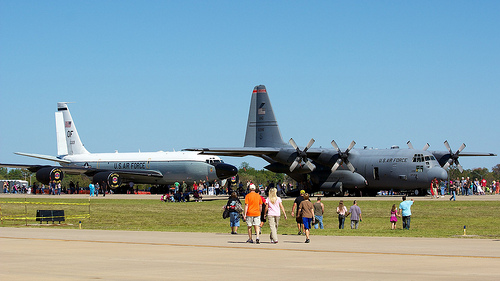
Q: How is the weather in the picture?
A: It is clear.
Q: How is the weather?
A: It is clear.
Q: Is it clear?
A: Yes, it is clear.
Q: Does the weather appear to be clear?
A: Yes, it is clear.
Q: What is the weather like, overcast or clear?
A: It is clear.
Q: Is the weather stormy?
A: No, it is clear.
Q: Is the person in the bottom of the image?
A: Yes, the person is in the bottom of the image.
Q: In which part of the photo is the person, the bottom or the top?
A: The person is in the bottom of the image.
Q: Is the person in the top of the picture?
A: No, the person is in the bottom of the image.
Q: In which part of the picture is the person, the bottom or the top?
A: The person is in the bottom of the image.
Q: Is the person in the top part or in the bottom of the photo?
A: The person is in the bottom of the image.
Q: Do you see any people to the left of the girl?
A: Yes, there is a person to the left of the girl.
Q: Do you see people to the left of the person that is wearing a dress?
A: Yes, there is a person to the left of the girl.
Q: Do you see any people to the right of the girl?
A: No, the person is to the left of the girl.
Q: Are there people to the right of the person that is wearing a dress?
A: No, the person is to the left of the girl.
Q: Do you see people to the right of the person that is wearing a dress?
A: No, the person is to the left of the girl.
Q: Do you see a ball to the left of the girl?
A: No, there is a person to the left of the girl.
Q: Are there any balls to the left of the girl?
A: No, there is a person to the left of the girl.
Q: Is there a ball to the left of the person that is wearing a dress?
A: No, there is a person to the left of the girl.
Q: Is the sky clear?
A: Yes, the sky is clear.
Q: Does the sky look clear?
A: Yes, the sky is clear.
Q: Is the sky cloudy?
A: No, the sky is clear.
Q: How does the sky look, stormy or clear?
A: The sky is clear.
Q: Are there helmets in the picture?
A: No, there are no helmets.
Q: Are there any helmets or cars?
A: No, there are no helmets or cars.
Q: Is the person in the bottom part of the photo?
A: Yes, the person is in the bottom of the image.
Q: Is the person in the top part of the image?
A: No, the person is in the bottom of the image.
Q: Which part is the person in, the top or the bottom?
A: The person is in the bottom of the image.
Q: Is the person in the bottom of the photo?
A: Yes, the person is in the bottom of the image.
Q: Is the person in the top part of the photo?
A: No, the person is in the bottom of the image.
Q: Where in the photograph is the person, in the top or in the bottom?
A: The person is in the bottom of the image.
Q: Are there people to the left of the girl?
A: Yes, there is a person to the left of the girl.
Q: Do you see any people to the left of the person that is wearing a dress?
A: Yes, there is a person to the left of the girl.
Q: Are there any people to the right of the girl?
A: No, the person is to the left of the girl.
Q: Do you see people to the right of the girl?
A: No, the person is to the left of the girl.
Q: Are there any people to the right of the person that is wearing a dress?
A: No, the person is to the left of the girl.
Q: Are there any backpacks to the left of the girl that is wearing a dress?
A: No, there is a person to the left of the girl.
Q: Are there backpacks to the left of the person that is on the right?
A: No, there is a person to the left of the girl.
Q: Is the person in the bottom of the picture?
A: Yes, the person is in the bottom of the image.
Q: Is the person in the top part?
A: No, the person is in the bottom of the image.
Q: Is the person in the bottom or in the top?
A: The person is in the bottom of the image.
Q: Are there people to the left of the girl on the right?
A: Yes, there is a person to the left of the girl.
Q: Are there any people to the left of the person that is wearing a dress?
A: Yes, there is a person to the left of the girl.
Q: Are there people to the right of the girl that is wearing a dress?
A: No, the person is to the left of the girl.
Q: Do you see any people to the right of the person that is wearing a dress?
A: No, the person is to the left of the girl.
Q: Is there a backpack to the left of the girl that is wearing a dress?
A: No, there is a person to the left of the girl.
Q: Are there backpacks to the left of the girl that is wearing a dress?
A: No, there is a person to the left of the girl.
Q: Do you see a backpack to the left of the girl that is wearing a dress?
A: No, there is a person to the left of the girl.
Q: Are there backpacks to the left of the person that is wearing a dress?
A: No, there is a person to the left of the girl.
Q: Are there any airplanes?
A: Yes, there is an airplane.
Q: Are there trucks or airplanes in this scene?
A: Yes, there is an airplane.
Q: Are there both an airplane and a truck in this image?
A: No, there is an airplane but no trucks.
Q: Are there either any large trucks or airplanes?
A: Yes, there is a large airplane.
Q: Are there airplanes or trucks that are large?
A: Yes, the airplane is large.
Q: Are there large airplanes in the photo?
A: Yes, there is a large airplane.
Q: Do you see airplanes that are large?
A: Yes, there is an airplane that is large.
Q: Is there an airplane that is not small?
A: Yes, there is a large airplane.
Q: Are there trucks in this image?
A: No, there are no trucks.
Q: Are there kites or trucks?
A: No, there are no trucks or kites.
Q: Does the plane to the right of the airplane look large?
A: Yes, the plane is large.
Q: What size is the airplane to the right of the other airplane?
A: The airplane is large.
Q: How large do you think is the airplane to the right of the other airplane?
A: The airplane is large.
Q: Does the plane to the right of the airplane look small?
A: No, the airplane is large.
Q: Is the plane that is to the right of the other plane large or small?
A: The plane is large.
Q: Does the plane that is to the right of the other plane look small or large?
A: The plane is large.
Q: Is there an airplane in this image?
A: Yes, there is an airplane.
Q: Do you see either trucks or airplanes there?
A: Yes, there is an airplane.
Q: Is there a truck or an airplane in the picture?
A: Yes, there is an airplane.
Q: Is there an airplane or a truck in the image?
A: Yes, there is an airplane.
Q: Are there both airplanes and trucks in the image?
A: No, there is an airplane but no trucks.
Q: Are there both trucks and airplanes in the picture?
A: No, there is an airplane but no trucks.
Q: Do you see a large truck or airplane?
A: Yes, there is a large airplane.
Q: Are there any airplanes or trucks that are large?
A: Yes, the airplane is large.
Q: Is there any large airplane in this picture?
A: Yes, there is a large airplane.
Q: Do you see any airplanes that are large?
A: Yes, there is an airplane that is large.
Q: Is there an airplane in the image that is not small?
A: Yes, there is a large airplane.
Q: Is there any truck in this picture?
A: No, there are no trucks.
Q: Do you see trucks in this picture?
A: No, there are no trucks.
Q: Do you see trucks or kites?
A: No, there are no trucks or kites.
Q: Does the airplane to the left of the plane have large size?
A: Yes, the airplane is large.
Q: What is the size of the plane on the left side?
A: The plane is large.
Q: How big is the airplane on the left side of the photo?
A: The plane is large.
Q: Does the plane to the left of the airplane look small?
A: No, the airplane is large.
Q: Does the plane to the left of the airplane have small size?
A: No, the airplane is large.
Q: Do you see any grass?
A: Yes, there is grass.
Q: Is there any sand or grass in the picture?
A: Yes, there is grass.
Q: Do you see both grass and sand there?
A: No, there is grass but no sand.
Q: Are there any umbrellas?
A: No, there are no umbrellas.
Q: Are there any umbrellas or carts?
A: No, there are no umbrellas or carts.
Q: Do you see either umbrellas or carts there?
A: No, there are no umbrellas or carts.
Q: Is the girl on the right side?
A: Yes, the girl is on the right of the image.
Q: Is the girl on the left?
A: No, the girl is on the right of the image.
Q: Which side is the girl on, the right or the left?
A: The girl is on the right of the image.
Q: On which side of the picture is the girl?
A: The girl is on the right of the image.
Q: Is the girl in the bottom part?
A: Yes, the girl is in the bottom of the image.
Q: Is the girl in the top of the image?
A: No, the girl is in the bottom of the image.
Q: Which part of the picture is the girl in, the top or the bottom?
A: The girl is in the bottom of the image.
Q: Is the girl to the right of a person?
A: Yes, the girl is to the right of a person.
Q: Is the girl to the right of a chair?
A: No, the girl is to the right of a person.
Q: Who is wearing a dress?
A: The girl is wearing a dress.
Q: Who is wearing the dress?
A: The girl is wearing a dress.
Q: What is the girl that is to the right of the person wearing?
A: The girl is wearing a dress.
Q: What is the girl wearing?
A: The girl is wearing a dress.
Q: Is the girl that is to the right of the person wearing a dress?
A: Yes, the girl is wearing a dress.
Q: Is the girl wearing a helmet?
A: No, the girl is wearing a dress.